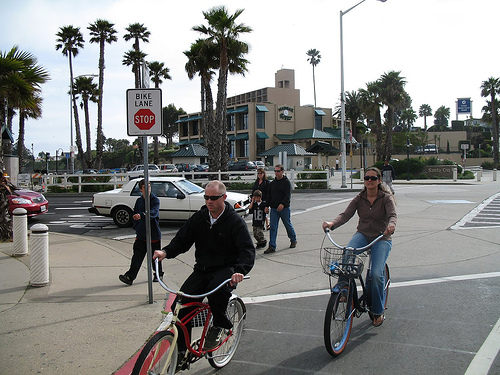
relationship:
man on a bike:
[145, 177, 256, 362] [126, 250, 253, 360]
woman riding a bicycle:
[320, 160, 401, 328] [320, 223, 390, 356]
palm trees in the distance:
[8, 5, 485, 177] [11, 8, 478, 180]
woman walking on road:
[320, 166, 397, 327] [0, 168, 499, 373]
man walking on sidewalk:
[116, 177, 163, 286] [0, 228, 218, 373]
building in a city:
[167, 62, 362, 180] [0, 9, 496, 373]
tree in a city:
[120, 13, 154, 170] [0, 9, 496, 373]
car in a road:
[85, 169, 253, 228] [0, 168, 499, 373]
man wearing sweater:
[116, 173, 166, 286] [131, 196, 160, 241]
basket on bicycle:
[322, 242, 365, 277] [320, 223, 392, 353]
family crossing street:
[243, 156, 297, 254] [20, 178, 499, 373]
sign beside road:
[123, 84, 163, 135] [34, 180, 494, 370]